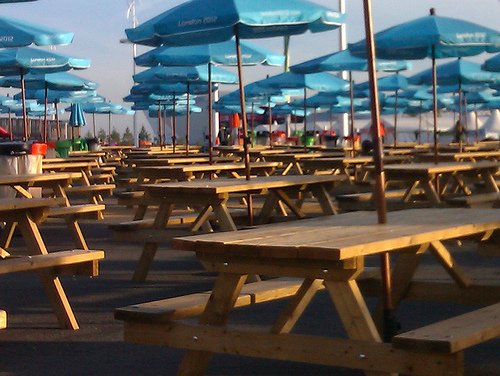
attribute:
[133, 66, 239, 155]
umbrella — blue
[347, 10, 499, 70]
umbrella — blue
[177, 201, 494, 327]
table — wooden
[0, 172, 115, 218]
table — vacant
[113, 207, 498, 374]
table — wood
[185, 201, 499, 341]
table — vacant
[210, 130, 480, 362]
table — unoccupied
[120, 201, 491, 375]
picnic table — unpainted, wooden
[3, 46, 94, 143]
umbrella — blue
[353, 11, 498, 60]
umbrella — blue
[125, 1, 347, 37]
umbrella — blue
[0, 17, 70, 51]
umbrella — blue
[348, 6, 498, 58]
umbrella — blue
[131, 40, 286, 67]
umbrella — blue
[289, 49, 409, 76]
umbrella — blue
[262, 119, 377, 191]
nail — metal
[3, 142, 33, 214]
trash can — black, orange, white 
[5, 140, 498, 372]
picnic benches — wooden